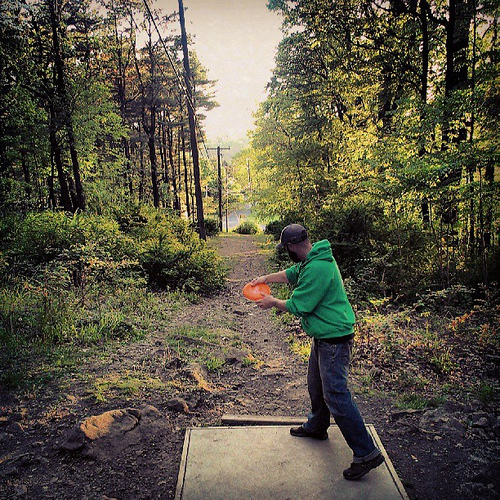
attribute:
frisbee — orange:
[237, 275, 273, 307]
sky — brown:
[213, 29, 262, 91]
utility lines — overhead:
[99, 0, 241, 190]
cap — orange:
[266, 213, 316, 251]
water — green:
[215, 208, 267, 232]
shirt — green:
[270, 235, 364, 360]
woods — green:
[5, 0, 220, 372]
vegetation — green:
[339, 192, 454, 284]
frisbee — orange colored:
[220, 276, 275, 312]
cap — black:
[261, 214, 316, 242]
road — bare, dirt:
[6, 226, 496, 497]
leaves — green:
[79, 107, 117, 147]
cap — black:
[274, 224, 309, 251]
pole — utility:
[212, 148, 232, 215]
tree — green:
[427, 0, 486, 288]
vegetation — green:
[24, 207, 140, 255]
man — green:
[248, 218, 389, 483]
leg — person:
[314, 336, 380, 463]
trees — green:
[239, 0, 496, 327]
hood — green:
[305, 238, 336, 265]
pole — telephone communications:
[205, 146, 230, 232]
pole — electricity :
[167, 3, 207, 250]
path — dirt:
[219, 235, 276, 415]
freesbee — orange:
[224, 268, 296, 315]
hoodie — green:
[279, 238, 357, 338]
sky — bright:
[0, 0, 498, 142]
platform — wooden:
[141, 391, 441, 498]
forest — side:
[7, 20, 483, 411]